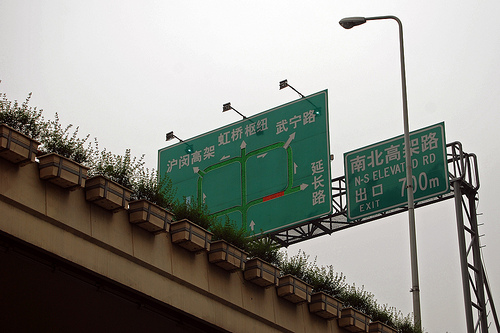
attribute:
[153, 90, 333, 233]
sign — green, large, white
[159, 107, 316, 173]
writing — chinese, white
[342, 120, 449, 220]
sign — green, chinese, english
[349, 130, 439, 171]
writing — chinese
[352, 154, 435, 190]
writing — english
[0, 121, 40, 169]
planter — brown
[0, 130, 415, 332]
roadway — brown, concrete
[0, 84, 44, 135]
plant — green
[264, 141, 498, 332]
sign support — metal, gray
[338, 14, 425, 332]
street lamp — metal, off, high, silver, thin, gray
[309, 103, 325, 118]
light — green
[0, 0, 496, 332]
sky — gray, cloudy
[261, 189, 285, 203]
mark — red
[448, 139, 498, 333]
ladder — gray, metal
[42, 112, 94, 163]
plant — green